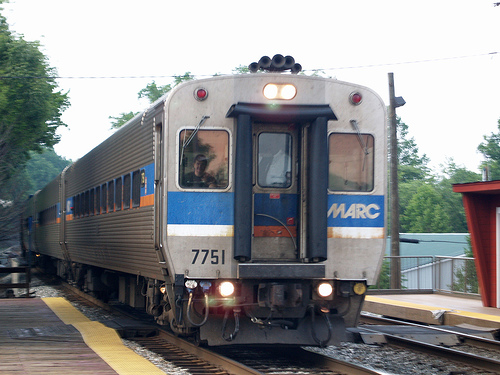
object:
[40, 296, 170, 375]
yellow line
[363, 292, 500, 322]
yellow line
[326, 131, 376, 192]
window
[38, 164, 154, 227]
stripe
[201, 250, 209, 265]
number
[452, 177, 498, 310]
building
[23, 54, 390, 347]
train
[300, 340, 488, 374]
gravel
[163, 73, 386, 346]
metal fence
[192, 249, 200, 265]
number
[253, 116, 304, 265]
door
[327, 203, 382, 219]
name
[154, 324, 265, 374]
tracks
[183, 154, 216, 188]
man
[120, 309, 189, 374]
gravel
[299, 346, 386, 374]
tracks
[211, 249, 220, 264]
number "7"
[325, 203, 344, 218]
letter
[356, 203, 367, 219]
letter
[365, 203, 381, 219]
letter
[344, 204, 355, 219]
letter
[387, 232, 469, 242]
roof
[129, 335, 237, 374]
stripe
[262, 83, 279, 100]
light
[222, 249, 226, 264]
numbers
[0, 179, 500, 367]
station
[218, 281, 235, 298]
light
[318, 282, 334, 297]
light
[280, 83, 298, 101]
light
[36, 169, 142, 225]
windows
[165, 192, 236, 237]
stripe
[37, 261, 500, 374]
tracks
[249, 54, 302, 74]
horn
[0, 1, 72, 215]
tree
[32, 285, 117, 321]
ground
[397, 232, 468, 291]
building